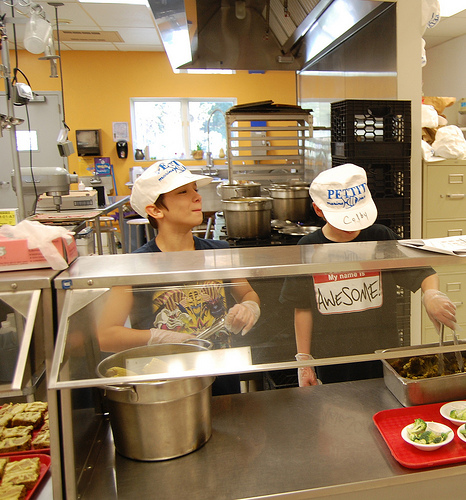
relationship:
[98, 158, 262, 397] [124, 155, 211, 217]
person wears cap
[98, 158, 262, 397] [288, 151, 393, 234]
person wears cap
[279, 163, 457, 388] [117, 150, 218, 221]
boy wears cap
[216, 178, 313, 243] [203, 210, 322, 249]
pots over stove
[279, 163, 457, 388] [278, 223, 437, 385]
boy wearing t-shirt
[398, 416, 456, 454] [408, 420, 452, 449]
bowl has broccoli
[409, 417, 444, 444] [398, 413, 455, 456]
broccoli on bowl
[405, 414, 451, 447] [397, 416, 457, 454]
lemons on plate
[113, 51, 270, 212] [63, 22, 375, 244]
window on building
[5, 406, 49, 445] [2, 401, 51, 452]
bread on tray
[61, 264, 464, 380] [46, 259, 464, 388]
glass on shelf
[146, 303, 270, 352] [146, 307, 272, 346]
gloves on hands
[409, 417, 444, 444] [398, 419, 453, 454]
broccoli on dish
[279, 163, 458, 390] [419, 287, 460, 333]
boy wearing gloves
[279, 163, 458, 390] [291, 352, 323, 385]
boy wearing gloves